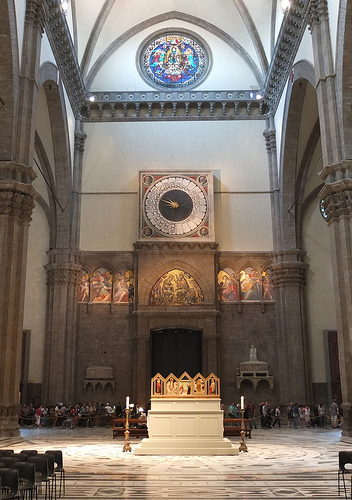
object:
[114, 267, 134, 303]
paintings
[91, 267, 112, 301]
paintings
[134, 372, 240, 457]
religious alter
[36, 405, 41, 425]
people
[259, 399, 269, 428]
person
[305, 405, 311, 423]
person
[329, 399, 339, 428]
person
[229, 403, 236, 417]
person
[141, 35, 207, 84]
painting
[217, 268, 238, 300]
art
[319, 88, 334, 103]
ground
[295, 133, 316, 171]
ground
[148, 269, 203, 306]
painting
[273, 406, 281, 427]
people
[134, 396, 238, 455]
altar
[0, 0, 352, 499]
building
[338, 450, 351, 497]
chair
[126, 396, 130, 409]
candle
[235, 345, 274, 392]
statue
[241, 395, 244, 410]
candle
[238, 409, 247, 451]
holder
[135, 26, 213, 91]
window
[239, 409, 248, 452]
stand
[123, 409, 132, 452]
stand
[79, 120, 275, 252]
wall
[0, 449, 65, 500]
chairs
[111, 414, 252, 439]
pedestal